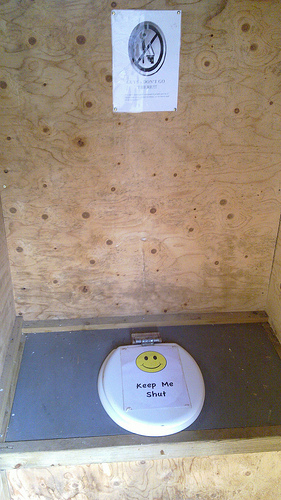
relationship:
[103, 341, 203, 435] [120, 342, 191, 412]
lid has sign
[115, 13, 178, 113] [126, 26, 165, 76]
notice says what is not allowed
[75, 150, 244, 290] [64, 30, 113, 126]
wall has knotholes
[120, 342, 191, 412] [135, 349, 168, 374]
sign has face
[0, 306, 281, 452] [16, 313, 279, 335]
frame made from wooden strips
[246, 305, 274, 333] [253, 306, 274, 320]
corner has tacks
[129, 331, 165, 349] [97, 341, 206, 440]
hinge connects lid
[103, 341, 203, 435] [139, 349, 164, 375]
lid has yellow face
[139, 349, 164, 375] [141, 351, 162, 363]
face has black eyes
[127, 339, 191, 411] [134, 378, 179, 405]
sign says keep me shut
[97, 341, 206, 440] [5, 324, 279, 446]
lid has seat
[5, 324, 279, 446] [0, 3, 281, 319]
toilet area has surrounding wall